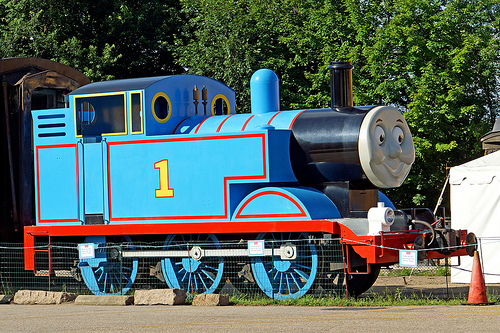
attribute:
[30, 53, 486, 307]
train — blue yellow red, red, blue, parked, blue red, black, large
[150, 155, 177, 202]
number — large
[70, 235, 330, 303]
wheels — blue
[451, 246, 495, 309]
cone — orange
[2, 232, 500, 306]
fence — metal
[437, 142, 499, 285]
building — white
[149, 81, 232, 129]
windows — round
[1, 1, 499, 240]
trees — green